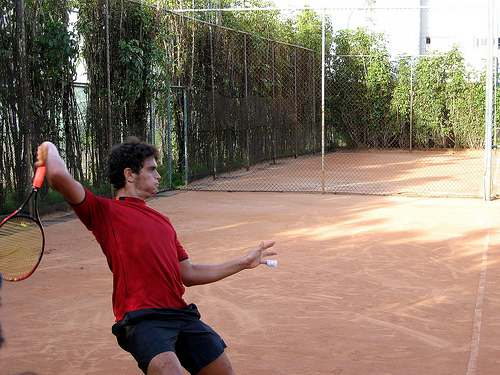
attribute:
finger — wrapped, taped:
[263, 259, 266, 265]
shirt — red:
[104, 205, 177, 297]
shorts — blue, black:
[112, 308, 232, 367]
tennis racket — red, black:
[1, 172, 50, 289]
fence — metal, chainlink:
[203, 53, 318, 118]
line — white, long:
[469, 267, 493, 317]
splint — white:
[259, 256, 285, 274]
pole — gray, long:
[313, 15, 334, 164]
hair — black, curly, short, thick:
[120, 135, 144, 161]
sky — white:
[362, 16, 408, 37]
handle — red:
[30, 170, 48, 185]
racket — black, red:
[3, 177, 54, 228]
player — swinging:
[65, 130, 243, 303]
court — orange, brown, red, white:
[224, 201, 345, 231]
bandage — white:
[258, 253, 279, 269]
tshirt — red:
[98, 210, 152, 265]